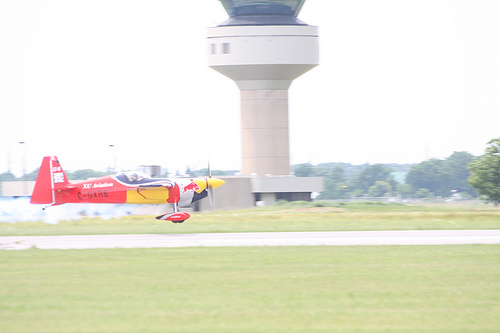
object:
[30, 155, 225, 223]
plane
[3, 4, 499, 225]
air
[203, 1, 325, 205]
tower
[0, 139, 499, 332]
airport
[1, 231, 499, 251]
runway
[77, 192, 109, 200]
letters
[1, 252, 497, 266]
grass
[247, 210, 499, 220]
ground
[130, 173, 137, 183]
pilot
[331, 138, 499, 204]
trees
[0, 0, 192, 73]
sky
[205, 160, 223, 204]
propeller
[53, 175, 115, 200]
decals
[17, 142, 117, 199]
lights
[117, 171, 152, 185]
cockpit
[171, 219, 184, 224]
wheels